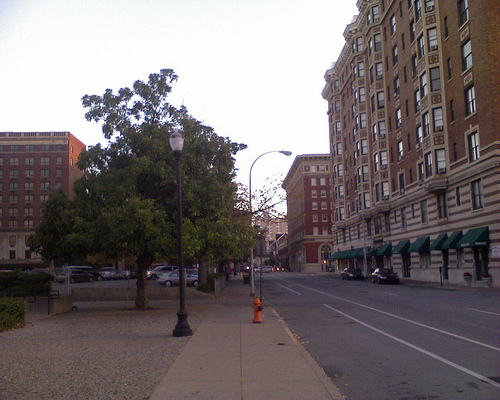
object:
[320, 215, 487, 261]
awnings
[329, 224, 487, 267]
shades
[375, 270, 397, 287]
cars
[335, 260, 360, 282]
cars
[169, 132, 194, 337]
street light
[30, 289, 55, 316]
stairwell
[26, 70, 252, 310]
tree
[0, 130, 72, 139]
writing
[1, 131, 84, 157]
side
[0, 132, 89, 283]
building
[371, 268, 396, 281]
car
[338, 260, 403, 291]
two cars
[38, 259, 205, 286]
cars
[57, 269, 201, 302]
parking lot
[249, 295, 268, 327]
hydrant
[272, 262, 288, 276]
car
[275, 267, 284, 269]
headlights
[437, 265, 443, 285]
parking meter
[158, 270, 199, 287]
car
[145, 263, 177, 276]
car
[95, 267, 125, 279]
car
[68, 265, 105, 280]
car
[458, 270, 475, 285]
woman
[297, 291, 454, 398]
line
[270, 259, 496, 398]
road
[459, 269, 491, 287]
flower pots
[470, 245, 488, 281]
outside door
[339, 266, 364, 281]
car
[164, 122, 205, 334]
light pole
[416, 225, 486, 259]
awnings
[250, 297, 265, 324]
fire hydrant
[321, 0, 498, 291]
building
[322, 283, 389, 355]
tarmacked road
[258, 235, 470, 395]
street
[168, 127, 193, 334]
lamp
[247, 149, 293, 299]
street light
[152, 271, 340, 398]
sidewalk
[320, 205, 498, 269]
building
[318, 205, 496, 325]
left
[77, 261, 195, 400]
street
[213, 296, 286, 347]
orange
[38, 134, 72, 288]
building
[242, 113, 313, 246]
top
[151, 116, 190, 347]
post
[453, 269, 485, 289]
planter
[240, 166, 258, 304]
pole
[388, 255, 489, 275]
windows